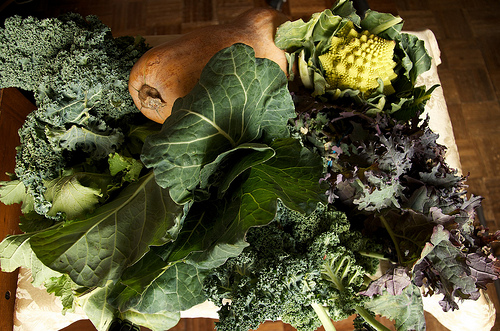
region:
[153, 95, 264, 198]
The lettuce is green.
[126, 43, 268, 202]
The leaf is large.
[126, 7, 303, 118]
The squash is under the lettuce.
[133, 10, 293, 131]
The squash is on the plate.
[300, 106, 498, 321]
The lettuce is purple.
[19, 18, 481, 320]
The vegetables are on the plate.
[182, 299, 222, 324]
The plate is white.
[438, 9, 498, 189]
The table is brown.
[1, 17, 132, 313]
The vegetables are green.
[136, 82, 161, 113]
The stem is short.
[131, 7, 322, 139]
small orange pumpkin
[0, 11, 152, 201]
green broccoli sticks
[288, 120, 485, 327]
purple romaine lettuce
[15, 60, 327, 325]
green fresh kale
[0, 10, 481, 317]
bunch of vegetables on table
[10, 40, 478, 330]
brown small table where vegetables are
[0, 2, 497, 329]
brown wooden floor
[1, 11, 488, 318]
healthy vegetables on a table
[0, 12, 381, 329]
green leaves on a table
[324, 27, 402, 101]
yellow vegetable in the corner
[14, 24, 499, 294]
A bunch of vegetables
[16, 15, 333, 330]
Greens from a garden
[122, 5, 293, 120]
A squash amongst greens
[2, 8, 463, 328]
Vegetable on a table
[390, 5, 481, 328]
A tablecloth on a table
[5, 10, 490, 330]
Vegetables on a tablecloth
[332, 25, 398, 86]
A yellow vegetable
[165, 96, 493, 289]
Leafy vegetables on a table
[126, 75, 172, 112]
The stem of a squash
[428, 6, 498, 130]
Wooden flooring under the table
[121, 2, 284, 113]
a large orange squash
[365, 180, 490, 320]
some purple letuce leaves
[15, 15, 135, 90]
some green brocolli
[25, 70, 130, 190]
some green brocolie leaves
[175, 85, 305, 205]
some green salad leaves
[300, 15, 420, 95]
some yellow vegtable and leaves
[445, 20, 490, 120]
some wooden flooring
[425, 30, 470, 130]
some white table cloth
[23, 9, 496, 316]
a table full of green vegetables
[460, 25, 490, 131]
some square floor patterns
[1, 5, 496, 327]
fresh green vegetables on a tray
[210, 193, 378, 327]
head portion of broccoli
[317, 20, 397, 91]
yellow spikey vegetable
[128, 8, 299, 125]
light brown color vegetable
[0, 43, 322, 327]
green lettuce leaf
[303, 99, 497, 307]
purple and green lettuc leaf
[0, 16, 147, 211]
head portion of broccoli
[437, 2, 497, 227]
brown laminate flooring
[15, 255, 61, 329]
white colored fabric under vegetables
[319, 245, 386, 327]
stem of vegetable leaf